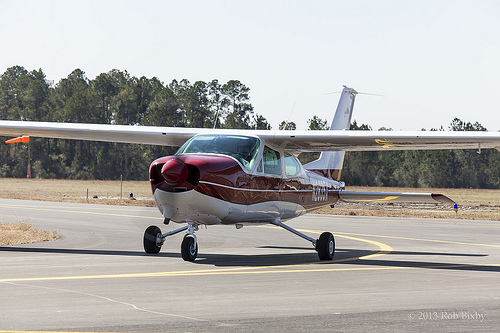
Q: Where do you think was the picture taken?
A: It was taken at the pavement.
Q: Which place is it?
A: It is a pavement.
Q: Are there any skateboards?
A: No, there are no skateboards.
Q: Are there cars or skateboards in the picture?
A: No, there are no skateboards or cars.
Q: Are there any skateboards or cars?
A: No, there are no skateboards or cars.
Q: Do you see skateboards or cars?
A: No, there are no skateboards or cars.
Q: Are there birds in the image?
A: No, there are no birds.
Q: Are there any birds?
A: No, there are no birds.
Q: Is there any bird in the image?
A: No, there are no birds.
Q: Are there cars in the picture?
A: No, there are no cars.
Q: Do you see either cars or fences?
A: No, there are no cars or fences.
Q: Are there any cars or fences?
A: No, there are no cars or fences.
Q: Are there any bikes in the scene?
A: No, there are no bikes.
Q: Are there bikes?
A: No, there are no bikes.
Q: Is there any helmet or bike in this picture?
A: No, there are no bikes or helmets.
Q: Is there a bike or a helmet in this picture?
A: No, there are no bikes or helmets.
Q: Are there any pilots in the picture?
A: No, there are no pilots.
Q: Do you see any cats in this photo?
A: No, there are no cats.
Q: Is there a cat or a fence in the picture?
A: No, there are no cats or fences.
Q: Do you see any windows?
A: Yes, there is a window.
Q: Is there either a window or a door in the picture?
A: Yes, there is a window.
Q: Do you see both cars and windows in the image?
A: No, there is a window but no cars.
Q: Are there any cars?
A: No, there are no cars.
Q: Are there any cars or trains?
A: No, there are no cars or trains.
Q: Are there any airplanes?
A: Yes, there is an airplane.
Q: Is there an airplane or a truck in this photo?
A: Yes, there is an airplane.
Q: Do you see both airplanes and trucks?
A: No, there is an airplane but no trucks.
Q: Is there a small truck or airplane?
A: Yes, there is a small airplane.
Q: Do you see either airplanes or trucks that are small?
A: Yes, the airplane is small.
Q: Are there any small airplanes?
A: Yes, there is a small airplane.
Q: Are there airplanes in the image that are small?
A: Yes, there is an airplane that is small.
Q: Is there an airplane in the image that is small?
A: Yes, there is an airplane that is small.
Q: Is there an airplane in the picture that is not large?
A: Yes, there is a small airplane.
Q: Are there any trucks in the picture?
A: No, there are no trucks.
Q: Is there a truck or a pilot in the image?
A: No, there are no trucks or pilots.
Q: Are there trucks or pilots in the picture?
A: No, there are no trucks or pilots.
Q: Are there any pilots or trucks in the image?
A: No, there are no trucks or pilots.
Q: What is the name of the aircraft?
A: The aircraft is an airplane.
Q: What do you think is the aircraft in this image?
A: The aircraft is an airplane.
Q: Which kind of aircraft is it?
A: The aircraft is an airplane.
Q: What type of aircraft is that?
A: This is an airplane.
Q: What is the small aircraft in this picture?
A: The aircraft is an airplane.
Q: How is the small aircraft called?
A: The aircraft is an airplane.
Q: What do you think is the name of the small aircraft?
A: The aircraft is an airplane.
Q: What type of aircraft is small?
A: The aircraft is an airplane.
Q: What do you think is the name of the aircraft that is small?
A: The aircraft is an airplane.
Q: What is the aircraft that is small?
A: The aircraft is an airplane.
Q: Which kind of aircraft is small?
A: The aircraft is an airplane.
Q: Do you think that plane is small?
A: Yes, the plane is small.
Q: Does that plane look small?
A: Yes, the plane is small.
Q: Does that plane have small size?
A: Yes, the plane is small.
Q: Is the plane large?
A: No, the plane is small.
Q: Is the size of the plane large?
A: No, the plane is small.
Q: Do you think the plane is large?
A: No, the plane is small.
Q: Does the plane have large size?
A: No, the plane is small.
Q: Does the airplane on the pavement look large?
A: No, the plane is small.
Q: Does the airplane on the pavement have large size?
A: No, the plane is small.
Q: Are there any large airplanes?
A: No, there is an airplane but it is small.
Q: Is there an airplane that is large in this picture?
A: No, there is an airplane but it is small.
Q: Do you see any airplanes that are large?
A: No, there is an airplane but it is small.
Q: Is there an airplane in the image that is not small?
A: No, there is an airplane but it is small.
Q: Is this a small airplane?
A: Yes, this is a small airplane.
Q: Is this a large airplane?
A: No, this is a small airplane.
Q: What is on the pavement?
A: The airplane is on the pavement.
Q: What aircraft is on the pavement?
A: The aircraft is an airplane.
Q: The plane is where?
A: The plane is on the pavement.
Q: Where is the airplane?
A: The plane is on the pavement.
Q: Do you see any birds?
A: No, there are no birds.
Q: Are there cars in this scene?
A: No, there are no cars.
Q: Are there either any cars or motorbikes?
A: No, there are no cars or motorbikes.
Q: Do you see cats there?
A: No, there are no cats.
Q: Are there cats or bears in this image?
A: No, there are no cats or bears.